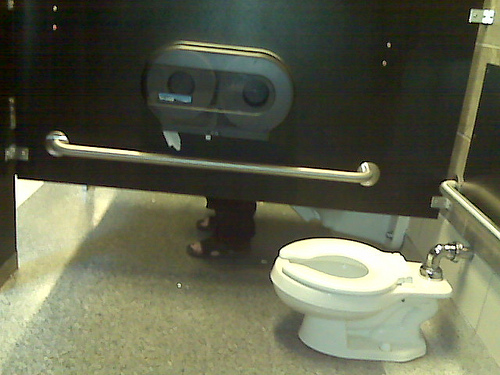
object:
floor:
[0, 173, 500, 375]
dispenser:
[141, 38, 293, 143]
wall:
[0, 0, 484, 219]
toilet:
[269, 235, 467, 365]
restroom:
[0, 0, 500, 375]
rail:
[40, 130, 382, 188]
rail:
[437, 179, 500, 272]